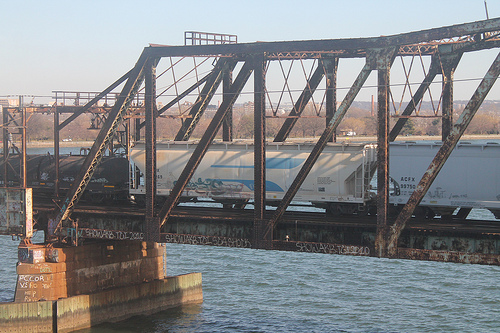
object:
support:
[0, 237, 205, 332]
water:
[0, 147, 499, 332]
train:
[0, 137, 499, 223]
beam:
[387, 51, 498, 252]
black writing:
[397, 174, 417, 182]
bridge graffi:
[294, 242, 371, 258]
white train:
[277, 151, 377, 194]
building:
[59, 137, 74, 142]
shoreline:
[0, 136, 500, 152]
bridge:
[30, 16, 499, 267]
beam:
[141, 18, 499, 58]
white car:
[373, 138, 499, 213]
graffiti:
[175, 222, 252, 238]